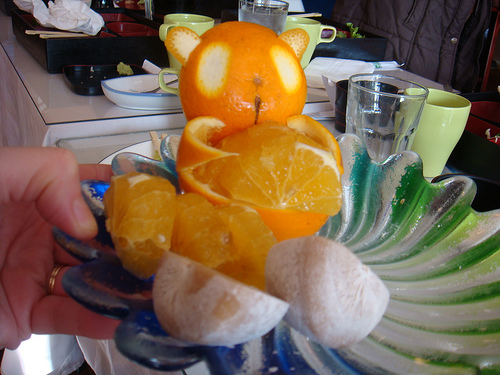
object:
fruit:
[103, 21, 391, 350]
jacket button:
[450, 37, 457, 44]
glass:
[237, 0, 289, 36]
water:
[239, 11, 288, 28]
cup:
[345, 72, 430, 163]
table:
[1, 14, 500, 375]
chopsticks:
[25, 30, 90, 39]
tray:
[11, 7, 171, 75]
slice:
[151, 251, 290, 347]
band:
[48, 265, 64, 295]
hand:
[0, 145, 147, 351]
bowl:
[51, 132, 500, 375]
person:
[0, 145, 176, 366]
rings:
[47, 264, 65, 295]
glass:
[345, 73, 429, 164]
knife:
[340, 68, 436, 156]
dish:
[101, 73, 183, 111]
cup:
[390, 87, 472, 178]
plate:
[50, 132, 500, 375]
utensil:
[25, 30, 90, 39]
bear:
[163, 20, 344, 242]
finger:
[44, 264, 154, 302]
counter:
[0, 12, 500, 375]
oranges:
[102, 20, 390, 350]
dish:
[51, 132, 500, 375]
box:
[10, 7, 171, 74]